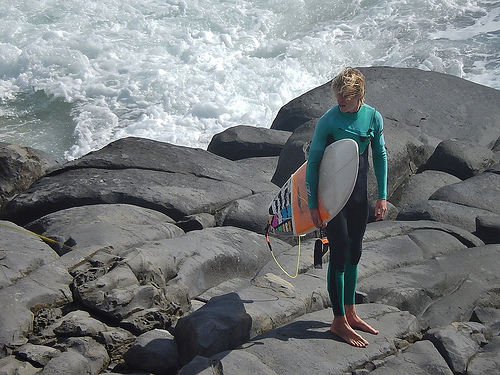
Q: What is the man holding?
A: Surfboard.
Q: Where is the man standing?
A: On large rocks.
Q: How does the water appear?
A: Rough.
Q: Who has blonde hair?
A: Surfer.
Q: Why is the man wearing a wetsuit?
A: To surf.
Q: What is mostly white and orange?
A: Surfboard.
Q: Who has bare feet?
A: The surfer.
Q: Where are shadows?
A: On the rocks.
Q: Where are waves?
A: In the water.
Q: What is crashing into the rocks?
A: Waves.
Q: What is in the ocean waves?
A: White foam.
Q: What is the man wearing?
A: Wetsuit.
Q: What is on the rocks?
A: Shadow of person.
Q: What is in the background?
A: Water.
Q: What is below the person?
A: Rocks.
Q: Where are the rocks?
A: Below the person.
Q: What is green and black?
A: Wetsuit.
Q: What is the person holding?
A: Surfboard.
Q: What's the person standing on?
A: Large rocks.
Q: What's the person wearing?
A: Wet suit.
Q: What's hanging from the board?
A: A chord.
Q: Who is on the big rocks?
A: A man.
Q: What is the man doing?
A: Standing.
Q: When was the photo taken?
A: Daytime.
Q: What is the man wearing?
A: A wetsuit.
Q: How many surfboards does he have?
A: One.